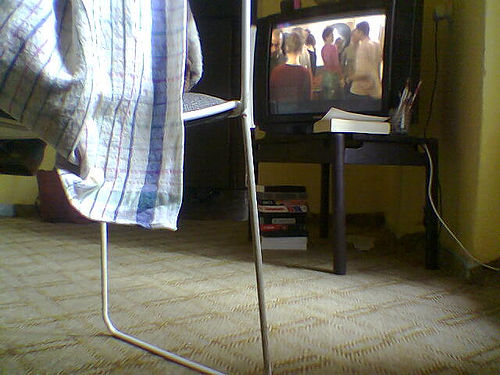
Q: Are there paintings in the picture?
A: No, there are no paintings.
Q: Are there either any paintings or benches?
A: No, there are no paintings or benches.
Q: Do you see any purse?
A: Yes, there is a purse.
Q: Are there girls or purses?
A: Yes, there is a purse.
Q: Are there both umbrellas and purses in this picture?
A: No, there is a purse but no umbrellas.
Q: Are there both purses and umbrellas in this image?
A: No, there is a purse but no umbrellas.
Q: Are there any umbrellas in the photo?
A: No, there are no umbrellas.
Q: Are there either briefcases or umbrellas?
A: No, there are no umbrellas or briefcases.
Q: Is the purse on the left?
A: Yes, the purse is on the left of the image.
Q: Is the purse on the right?
A: No, the purse is on the left of the image.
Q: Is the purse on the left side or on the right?
A: The purse is on the left of the image.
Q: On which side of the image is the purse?
A: The purse is on the left of the image.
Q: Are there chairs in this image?
A: Yes, there is a chair.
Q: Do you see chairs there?
A: Yes, there is a chair.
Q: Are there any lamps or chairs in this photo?
A: Yes, there is a chair.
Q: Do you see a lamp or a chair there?
A: Yes, there is a chair.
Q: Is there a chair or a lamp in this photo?
A: Yes, there is a chair.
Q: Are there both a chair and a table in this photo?
A: Yes, there are both a chair and a table.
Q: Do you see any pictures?
A: No, there are no pictures.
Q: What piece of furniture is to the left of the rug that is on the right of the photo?
A: The piece of furniture is a chair.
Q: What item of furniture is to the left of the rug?
A: The piece of furniture is a chair.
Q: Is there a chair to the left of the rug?
A: Yes, there is a chair to the left of the rug.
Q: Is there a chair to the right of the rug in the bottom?
A: No, the chair is to the left of the rug.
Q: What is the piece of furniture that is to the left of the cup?
A: The piece of furniture is a chair.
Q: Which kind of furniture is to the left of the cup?
A: The piece of furniture is a chair.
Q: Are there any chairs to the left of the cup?
A: Yes, there is a chair to the left of the cup.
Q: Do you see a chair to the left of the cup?
A: Yes, there is a chair to the left of the cup.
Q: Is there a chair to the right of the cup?
A: No, the chair is to the left of the cup.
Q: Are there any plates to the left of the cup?
A: No, there is a chair to the left of the cup.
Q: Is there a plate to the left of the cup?
A: No, there is a chair to the left of the cup.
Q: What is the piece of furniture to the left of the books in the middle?
A: The piece of furniture is a chair.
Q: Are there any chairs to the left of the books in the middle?
A: Yes, there is a chair to the left of the books.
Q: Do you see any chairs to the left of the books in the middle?
A: Yes, there is a chair to the left of the books.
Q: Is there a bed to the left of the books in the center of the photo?
A: No, there is a chair to the left of the books.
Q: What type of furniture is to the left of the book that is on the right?
A: The piece of furniture is a chair.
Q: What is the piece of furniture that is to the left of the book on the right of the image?
A: The piece of furniture is a chair.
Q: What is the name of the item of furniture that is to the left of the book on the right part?
A: The piece of furniture is a chair.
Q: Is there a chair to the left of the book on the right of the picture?
A: Yes, there is a chair to the left of the book.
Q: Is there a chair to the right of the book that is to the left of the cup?
A: No, the chair is to the left of the book.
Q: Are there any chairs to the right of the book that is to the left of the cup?
A: No, the chair is to the left of the book.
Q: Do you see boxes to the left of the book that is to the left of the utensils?
A: No, there is a chair to the left of the book.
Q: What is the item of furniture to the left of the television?
A: The piece of furniture is a chair.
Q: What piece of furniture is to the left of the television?
A: The piece of furniture is a chair.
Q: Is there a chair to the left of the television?
A: Yes, there is a chair to the left of the television.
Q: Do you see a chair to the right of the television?
A: No, the chair is to the left of the television.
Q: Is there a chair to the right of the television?
A: No, the chair is to the left of the television.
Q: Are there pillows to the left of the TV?
A: No, there is a chair to the left of the TV.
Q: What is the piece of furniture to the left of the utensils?
A: The piece of furniture is a chair.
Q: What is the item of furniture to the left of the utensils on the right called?
A: The piece of furniture is a chair.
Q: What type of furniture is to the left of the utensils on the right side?
A: The piece of furniture is a chair.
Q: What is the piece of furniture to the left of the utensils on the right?
A: The piece of furniture is a chair.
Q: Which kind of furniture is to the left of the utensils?
A: The piece of furniture is a chair.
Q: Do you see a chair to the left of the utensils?
A: Yes, there is a chair to the left of the utensils.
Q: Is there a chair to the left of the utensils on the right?
A: Yes, there is a chair to the left of the utensils.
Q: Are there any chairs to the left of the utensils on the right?
A: Yes, there is a chair to the left of the utensils.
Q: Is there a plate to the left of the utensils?
A: No, there is a chair to the left of the utensils.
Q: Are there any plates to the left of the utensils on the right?
A: No, there is a chair to the left of the utensils.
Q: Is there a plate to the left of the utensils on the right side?
A: No, there is a chair to the left of the utensils.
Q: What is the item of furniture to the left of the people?
A: The piece of furniture is a chair.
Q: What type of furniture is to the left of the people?
A: The piece of furniture is a chair.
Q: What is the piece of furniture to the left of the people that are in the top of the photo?
A: The piece of furniture is a chair.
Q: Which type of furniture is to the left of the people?
A: The piece of furniture is a chair.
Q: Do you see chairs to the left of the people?
A: Yes, there is a chair to the left of the people.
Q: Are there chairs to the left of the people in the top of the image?
A: Yes, there is a chair to the left of the people.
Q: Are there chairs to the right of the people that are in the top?
A: No, the chair is to the left of the people.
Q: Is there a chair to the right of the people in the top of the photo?
A: No, the chair is to the left of the people.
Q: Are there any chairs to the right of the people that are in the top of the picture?
A: No, the chair is to the left of the people.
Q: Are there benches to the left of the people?
A: No, there is a chair to the left of the people.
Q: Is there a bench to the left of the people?
A: No, there is a chair to the left of the people.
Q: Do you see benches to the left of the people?
A: No, there is a chair to the left of the people.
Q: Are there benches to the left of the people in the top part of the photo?
A: No, there is a chair to the left of the people.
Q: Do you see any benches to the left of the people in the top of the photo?
A: No, there is a chair to the left of the people.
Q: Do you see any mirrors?
A: No, there are no mirrors.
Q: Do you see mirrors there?
A: No, there are no mirrors.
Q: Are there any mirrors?
A: No, there are no mirrors.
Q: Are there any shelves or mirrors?
A: No, there are no mirrors or shelves.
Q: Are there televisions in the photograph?
A: Yes, there is a television.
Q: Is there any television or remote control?
A: Yes, there is a television.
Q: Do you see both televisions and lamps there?
A: No, there is a television but no lamps.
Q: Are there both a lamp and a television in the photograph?
A: No, there is a television but no lamps.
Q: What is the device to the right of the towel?
A: The device is a television.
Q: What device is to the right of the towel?
A: The device is a television.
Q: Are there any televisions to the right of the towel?
A: Yes, there is a television to the right of the towel.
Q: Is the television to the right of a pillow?
A: No, the television is to the right of the towel.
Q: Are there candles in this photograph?
A: No, there are no candles.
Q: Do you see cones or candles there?
A: No, there are no candles or cones.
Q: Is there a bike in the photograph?
A: No, there are no bikes.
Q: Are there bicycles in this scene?
A: No, there are no bicycles.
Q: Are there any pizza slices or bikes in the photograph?
A: No, there are no bikes or pizza slices.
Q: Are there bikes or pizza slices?
A: No, there are no bikes or pizza slices.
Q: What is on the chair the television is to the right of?
A: The seat is on the chair.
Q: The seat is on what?
A: The seat is on the chair.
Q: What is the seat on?
A: The seat is on the chair.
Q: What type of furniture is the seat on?
A: The seat is on the chair.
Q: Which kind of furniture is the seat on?
A: The seat is on the chair.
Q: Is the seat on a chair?
A: Yes, the seat is on a chair.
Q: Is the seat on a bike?
A: No, the seat is on a chair.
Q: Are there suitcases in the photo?
A: No, there are no suitcases.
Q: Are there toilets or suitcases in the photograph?
A: No, there are no suitcases or toilets.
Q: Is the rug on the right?
A: Yes, the rug is on the right of the image.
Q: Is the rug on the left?
A: No, the rug is on the right of the image.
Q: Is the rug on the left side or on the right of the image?
A: The rug is on the right of the image.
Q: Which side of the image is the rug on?
A: The rug is on the right of the image.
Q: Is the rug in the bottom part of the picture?
A: Yes, the rug is in the bottom of the image.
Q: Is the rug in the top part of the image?
A: No, the rug is in the bottom of the image.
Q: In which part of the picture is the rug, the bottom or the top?
A: The rug is in the bottom of the image.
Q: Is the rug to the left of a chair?
A: No, the rug is to the right of a chair.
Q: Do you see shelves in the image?
A: No, there are no shelves.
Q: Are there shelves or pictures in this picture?
A: No, there are no shelves or pictures.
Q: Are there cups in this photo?
A: Yes, there is a cup.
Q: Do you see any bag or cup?
A: Yes, there is a cup.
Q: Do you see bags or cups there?
A: Yes, there is a cup.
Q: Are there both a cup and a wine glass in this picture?
A: No, there is a cup but no wine glasses.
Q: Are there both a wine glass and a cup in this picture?
A: No, there is a cup but no wine glasses.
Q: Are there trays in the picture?
A: No, there are no trays.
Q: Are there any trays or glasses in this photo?
A: No, there are no trays or glasses.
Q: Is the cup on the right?
A: Yes, the cup is on the right of the image.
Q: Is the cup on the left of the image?
A: No, the cup is on the right of the image.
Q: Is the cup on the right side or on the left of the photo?
A: The cup is on the right of the image.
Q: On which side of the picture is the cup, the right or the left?
A: The cup is on the right of the image.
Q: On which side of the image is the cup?
A: The cup is on the right of the image.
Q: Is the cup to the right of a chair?
A: Yes, the cup is to the right of a chair.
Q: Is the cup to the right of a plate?
A: No, the cup is to the right of a chair.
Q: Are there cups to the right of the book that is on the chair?
A: Yes, there is a cup to the right of the book.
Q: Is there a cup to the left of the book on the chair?
A: No, the cup is to the right of the book.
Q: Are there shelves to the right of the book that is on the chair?
A: No, there is a cup to the right of the book.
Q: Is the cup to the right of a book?
A: Yes, the cup is to the right of a book.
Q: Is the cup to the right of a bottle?
A: No, the cup is to the right of a book.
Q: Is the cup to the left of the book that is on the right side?
A: No, the cup is to the right of the book.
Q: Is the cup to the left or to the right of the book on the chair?
A: The cup is to the right of the book.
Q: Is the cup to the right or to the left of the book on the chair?
A: The cup is to the right of the book.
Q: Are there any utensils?
A: Yes, there are utensils.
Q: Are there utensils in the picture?
A: Yes, there are utensils.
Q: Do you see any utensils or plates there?
A: Yes, there are utensils.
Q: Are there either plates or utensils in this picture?
A: Yes, there are utensils.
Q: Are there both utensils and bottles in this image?
A: No, there are utensils but no bottles.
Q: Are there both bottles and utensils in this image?
A: No, there are utensils but no bottles.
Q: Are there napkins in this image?
A: No, there are no napkins.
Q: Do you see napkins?
A: No, there are no napkins.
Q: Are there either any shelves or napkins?
A: No, there are no napkins or shelves.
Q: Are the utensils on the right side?
A: Yes, the utensils are on the right of the image.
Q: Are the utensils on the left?
A: No, the utensils are on the right of the image.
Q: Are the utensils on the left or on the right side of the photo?
A: The utensils are on the right of the image.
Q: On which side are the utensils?
A: The utensils are on the right of the image.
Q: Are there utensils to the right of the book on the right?
A: Yes, there are utensils to the right of the book.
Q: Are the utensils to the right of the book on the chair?
A: Yes, the utensils are to the right of the book.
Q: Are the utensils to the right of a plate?
A: No, the utensils are to the right of the book.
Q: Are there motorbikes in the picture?
A: No, there are no motorbikes.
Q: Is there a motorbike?
A: No, there are no motorcycles.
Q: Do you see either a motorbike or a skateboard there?
A: No, there are no motorcycles or skateboards.